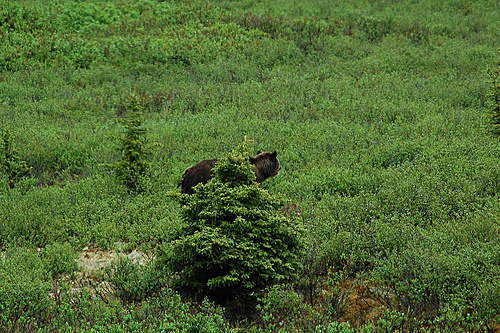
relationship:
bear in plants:
[176, 149, 282, 197] [0, 0, 499, 332]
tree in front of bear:
[160, 133, 308, 299] [176, 149, 282, 197]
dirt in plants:
[65, 240, 156, 287] [0, 0, 499, 332]